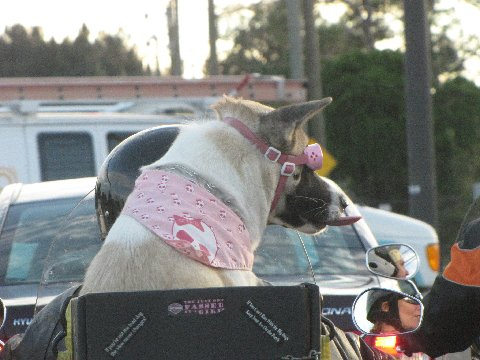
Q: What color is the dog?
A: White and brown.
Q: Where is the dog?
A: On a motorcycle.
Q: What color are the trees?
A: Green.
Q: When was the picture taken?
A: Daytime.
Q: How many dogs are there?
A: One.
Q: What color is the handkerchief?
A: Pink.